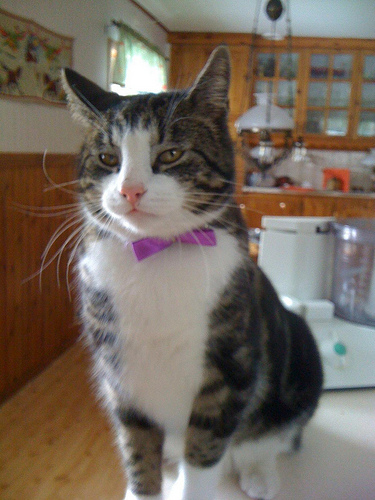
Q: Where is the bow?
A: On the cat.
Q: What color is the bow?
A: Pink.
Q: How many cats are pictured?
A: One.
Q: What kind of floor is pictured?
A: Wooden floor.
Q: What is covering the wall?
A: Wooden panel.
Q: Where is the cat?
A: On the counter.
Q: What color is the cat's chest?
A: White.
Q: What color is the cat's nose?
A: Pink.